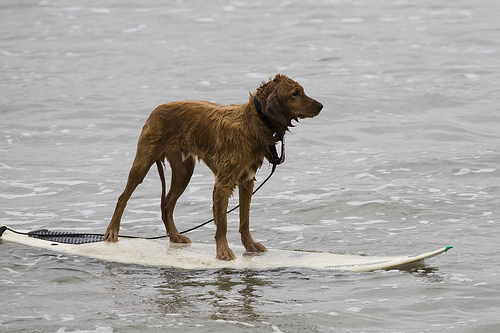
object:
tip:
[443, 240, 454, 257]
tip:
[315, 97, 325, 111]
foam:
[446, 167, 493, 179]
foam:
[295, 185, 348, 205]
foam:
[350, 161, 385, 186]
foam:
[338, 297, 377, 319]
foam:
[439, 262, 484, 292]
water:
[0, 5, 139, 58]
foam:
[281, 188, 346, 202]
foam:
[337, 302, 364, 314]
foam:
[453, 162, 497, 179]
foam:
[17, 259, 39, 271]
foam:
[344, 196, 390, 211]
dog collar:
[250, 94, 286, 147]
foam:
[55, 322, 113, 331]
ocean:
[329, 37, 455, 186]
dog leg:
[212, 161, 236, 260]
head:
[260, 72, 325, 128]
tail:
[154, 160, 168, 204]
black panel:
[25, 227, 107, 243]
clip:
[268, 127, 290, 164]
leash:
[32, 140, 287, 238]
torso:
[136, 95, 258, 169]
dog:
[100, 72, 328, 262]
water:
[240, 0, 499, 74]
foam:
[268, 322, 280, 331]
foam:
[414, 217, 441, 229]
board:
[0, 223, 458, 275]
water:
[4, 248, 154, 330]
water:
[145, 274, 417, 326]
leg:
[102, 145, 157, 245]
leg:
[160, 162, 195, 244]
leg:
[211, 173, 238, 262]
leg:
[237, 185, 269, 255]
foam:
[269, 213, 316, 235]